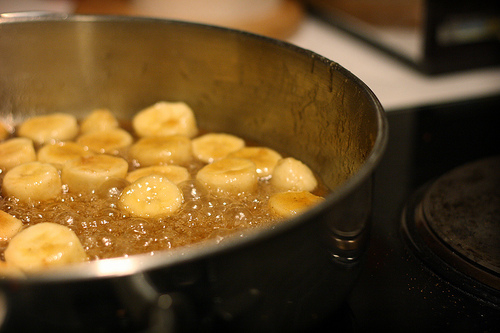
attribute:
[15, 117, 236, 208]
bananas — tan 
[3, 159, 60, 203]
banana —  cooking,  in slice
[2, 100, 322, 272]
caramelized bananas —  Carmalized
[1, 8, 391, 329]
frying pan —  for frying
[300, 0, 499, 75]
appliance — black 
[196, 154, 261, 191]
food — in slice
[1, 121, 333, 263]
liquid —  bubbling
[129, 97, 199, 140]
banana —  in slice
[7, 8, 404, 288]
pot —  in  use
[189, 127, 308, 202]
banana —  cooking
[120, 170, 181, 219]
banana slice —  cooking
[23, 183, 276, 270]
bubbles — brown 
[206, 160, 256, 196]
banana slice —  Boiling, of banana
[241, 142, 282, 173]
banana slice —  Boiling, of banana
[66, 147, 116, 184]
banana slice —  Boiling, of banana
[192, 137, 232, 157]
banana slice —  Boiling, of banana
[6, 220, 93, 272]
banana slice —  Boiling, of banana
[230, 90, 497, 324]
stove —  in  use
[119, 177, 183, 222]
food slice — of food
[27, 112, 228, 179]
banana —  cooking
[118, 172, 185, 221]
food — in slice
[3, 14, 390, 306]
pan —  for saute, for saute 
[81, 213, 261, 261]
sauce —  with bubbles,  boiling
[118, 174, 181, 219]
banana —  in slice,  cooking